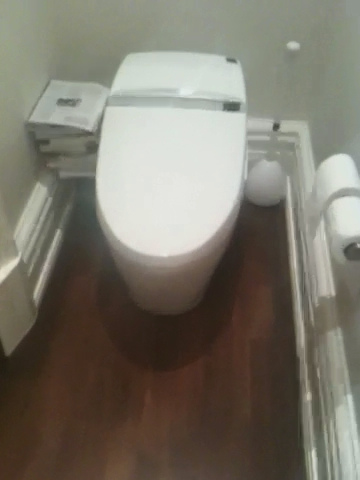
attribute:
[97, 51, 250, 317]
toliet — large, white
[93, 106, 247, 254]
lid — down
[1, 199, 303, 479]
floor — wooden, dark wood, wood, hard wood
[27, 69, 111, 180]
newspaper — stacked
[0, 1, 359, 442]
wall — small, grey, tan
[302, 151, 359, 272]
toliet paper — rolled, roll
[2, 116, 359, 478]
border — white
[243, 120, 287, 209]
toilet bowl cleaner — white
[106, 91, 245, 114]
stripe — grey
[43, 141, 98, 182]
books — stacked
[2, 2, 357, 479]
bathroom — a interior shot, a view from above, clean, cramped, white